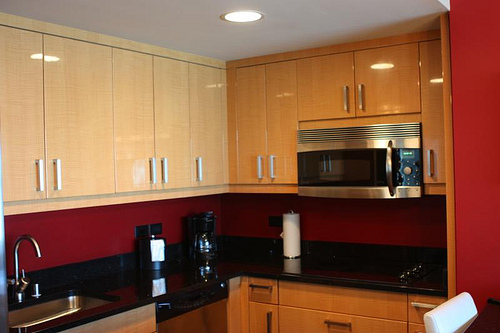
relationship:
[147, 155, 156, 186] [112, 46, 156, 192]
handle on front of cabinet door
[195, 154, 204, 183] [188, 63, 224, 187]
handle on front of cabinet door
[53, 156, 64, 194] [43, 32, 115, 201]
handle on front of cabinet door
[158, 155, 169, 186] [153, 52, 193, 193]
handle on front of cabinet door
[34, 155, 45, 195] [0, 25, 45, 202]
handle on front of cabinet door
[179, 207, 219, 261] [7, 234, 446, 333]
coffee maker on top of counter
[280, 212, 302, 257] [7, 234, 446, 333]
paper towels on top of counter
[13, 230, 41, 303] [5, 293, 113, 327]
faucet behind sink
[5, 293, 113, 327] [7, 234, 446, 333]
sink built into counter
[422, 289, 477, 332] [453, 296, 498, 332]
chair next to table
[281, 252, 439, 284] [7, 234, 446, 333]
stove on top of counter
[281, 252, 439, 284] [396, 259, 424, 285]
stove has knobs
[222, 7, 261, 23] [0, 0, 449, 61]
recessed light inside of ceiling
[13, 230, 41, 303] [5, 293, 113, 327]
faucet on back of sink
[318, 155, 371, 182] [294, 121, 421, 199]
window on door of microwave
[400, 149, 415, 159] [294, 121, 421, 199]
digital display on front of microwave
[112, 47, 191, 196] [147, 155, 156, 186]
cabinet has handle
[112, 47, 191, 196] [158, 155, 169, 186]
cabinet has handle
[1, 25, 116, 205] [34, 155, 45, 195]
cabinet has handle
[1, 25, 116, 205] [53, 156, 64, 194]
cabinet has handle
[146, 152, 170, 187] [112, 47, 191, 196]
handles on front of cabinet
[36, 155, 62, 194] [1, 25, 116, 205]
handles on front of cabinet